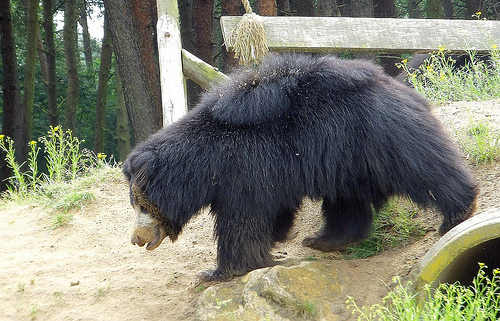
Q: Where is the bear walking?
A: Down hill.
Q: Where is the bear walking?
A: On the sand.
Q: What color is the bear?
A: Brown.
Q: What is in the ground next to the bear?
A: Cement tunnel.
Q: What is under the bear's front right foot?
A: Large rock.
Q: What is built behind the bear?
A: A wood play structure for the bear.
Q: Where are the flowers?
A: On the left.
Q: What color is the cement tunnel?
A: White.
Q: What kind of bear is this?
A: Black bear.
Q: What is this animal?
A: A bear.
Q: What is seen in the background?
A: Trees.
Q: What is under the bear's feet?
A: Dirt.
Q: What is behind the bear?
A: Wooden fence.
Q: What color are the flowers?
A: Yellow.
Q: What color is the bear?
A: Black.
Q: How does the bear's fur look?
A: Shaggy.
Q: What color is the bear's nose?
A: Tan.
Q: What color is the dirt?
A: Brown.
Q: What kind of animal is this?
A: A bear.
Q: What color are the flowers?
A: Yellow.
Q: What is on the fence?
A: A rope.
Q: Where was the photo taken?
A: The woods.